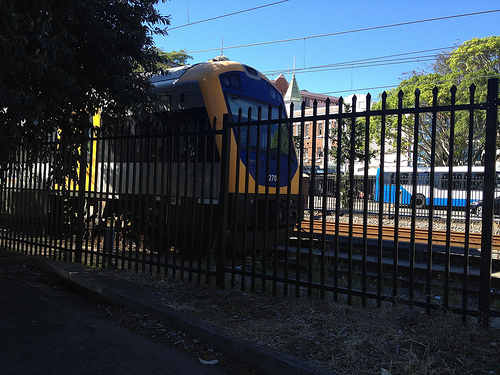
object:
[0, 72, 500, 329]
fence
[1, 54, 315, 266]
train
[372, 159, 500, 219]
bus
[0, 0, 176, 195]
tree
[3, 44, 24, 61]
leaves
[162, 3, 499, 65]
wires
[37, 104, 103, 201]
door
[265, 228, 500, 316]
tracks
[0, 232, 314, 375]
street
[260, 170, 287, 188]
numbers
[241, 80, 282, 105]
blue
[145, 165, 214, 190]
white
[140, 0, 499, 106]
sky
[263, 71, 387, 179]
buildings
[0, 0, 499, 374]
background